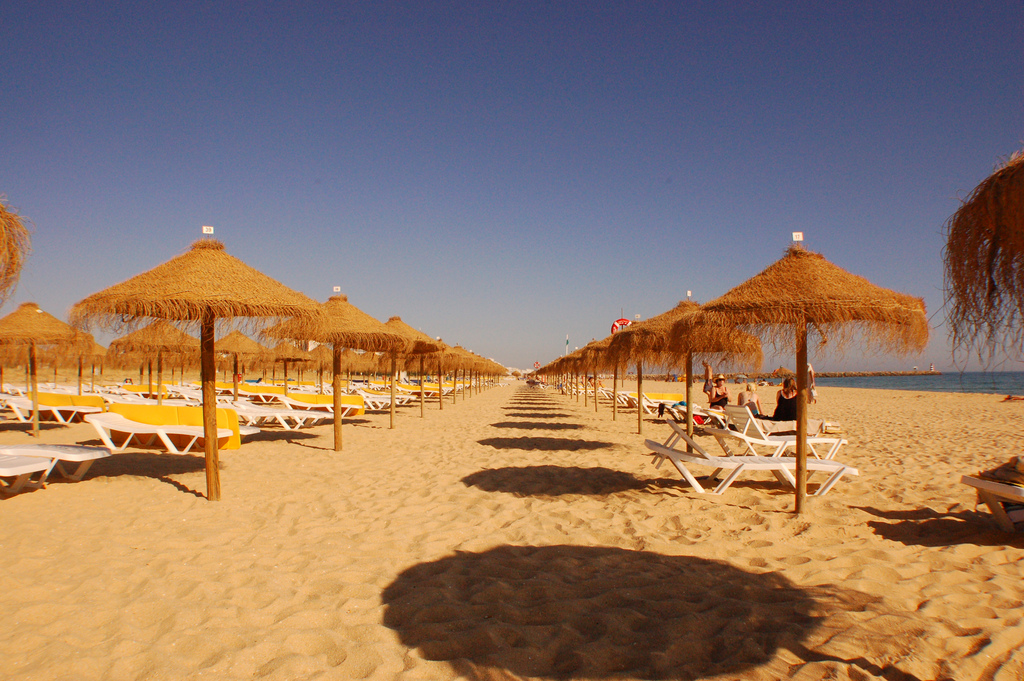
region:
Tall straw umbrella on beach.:
[81, 218, 301, 488]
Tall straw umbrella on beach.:
[290, 266, 377, 466]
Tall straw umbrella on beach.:
[370, 325, 425, 417]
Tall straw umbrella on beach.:
[644, 285, 749, 440]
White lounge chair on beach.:
[659, 427, 840, 495]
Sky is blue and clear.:
[68, 50, 894, 196]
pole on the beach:
[789, 474, 818, 513]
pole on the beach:
[178, 455, 230, 522]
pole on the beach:
[321, 423, 342, 461]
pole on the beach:
[689, 423, 693, 463]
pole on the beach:
[465, 373, 508, 390]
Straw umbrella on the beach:
[68, 127, 338, 527]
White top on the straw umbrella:
[694, 173, 911, 373]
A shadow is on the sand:
[443, 421, 912, 606]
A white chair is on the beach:
[633, 405, 1022, 605]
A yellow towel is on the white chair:
[46, 372, 306, 489]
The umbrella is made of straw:
[55, 171, 392, 599]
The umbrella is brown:
[645, 180, 959, 658]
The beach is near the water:
[552, 301, 1008, 536]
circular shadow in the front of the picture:
[376, 534, 833, 677]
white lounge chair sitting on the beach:
[91, 401, 193, 459]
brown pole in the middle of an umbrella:
[185, 299, 237, 521]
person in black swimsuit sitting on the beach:
[773, 356, 818, 423]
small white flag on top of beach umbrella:
[780, 220, 816, 256]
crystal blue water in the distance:
[960, 359, 1006, 391]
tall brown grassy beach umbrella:
[713, 215, 911, 514]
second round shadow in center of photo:
[451, 441, 670, 521]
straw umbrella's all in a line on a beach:
[509, 202, 930, 405]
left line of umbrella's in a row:
[53, 175, 537, 478]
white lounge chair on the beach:
[74, 398, 247, 463]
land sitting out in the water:
[868, 355, 951, 388]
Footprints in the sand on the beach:
[61, 544, 213, 671]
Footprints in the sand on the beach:
[46, 605, 202, 663]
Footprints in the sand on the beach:
[863, 558, 981, 635]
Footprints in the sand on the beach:
[881, 401, 962, 444]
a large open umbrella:
[73, 236, 307, 502]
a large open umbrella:
[272, 288, 408, 447]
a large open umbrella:
[11, 301, 87, 445]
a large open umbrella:
[700, 239, 923, 528]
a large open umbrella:
[623, 286, 748, 457]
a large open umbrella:
[608, 314, 669, 438]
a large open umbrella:
[213, 324, 262, 397]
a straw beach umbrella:
[704, 173, 974, 664]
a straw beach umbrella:
[660, 272, 782, 443]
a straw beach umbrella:
[580, 278, 616, 386]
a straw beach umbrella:
[164, 228, 264, 448]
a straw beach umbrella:
[299, 215, 361, 365]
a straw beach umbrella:
[401, 294, 458, 431]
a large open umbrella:
[80, 204, 330, 498]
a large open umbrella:
[275, 280, 409, 457]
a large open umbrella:
[358, 311, 426, 430]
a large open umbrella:
[398, 318, 434, 417]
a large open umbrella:
[99, 326, 198, 409]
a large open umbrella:
[199, 324, 273, 405]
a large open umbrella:
[246, 332, 311, 397]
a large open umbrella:
[608, 292, 770, 458]